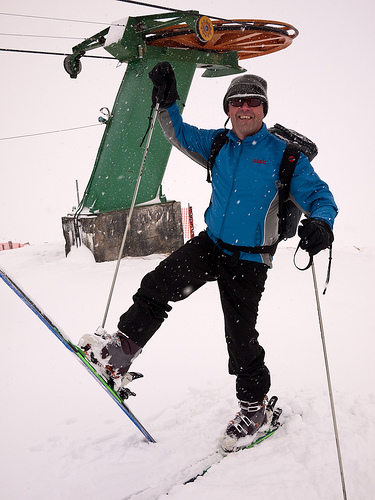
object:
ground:
[0, 241, 375, 500]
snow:
[0, 236, 375, 500]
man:
[78, 61, 338, 452]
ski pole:
[309, 250, 345, 500]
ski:
[63, 8, 297, 213]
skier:
[0, 61, 346, 500]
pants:
[116, 229, 271, 402]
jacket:
[156, 102, 336, 268]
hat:
[221, 73, 269, 115]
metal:
[62, 26, 111, 79]